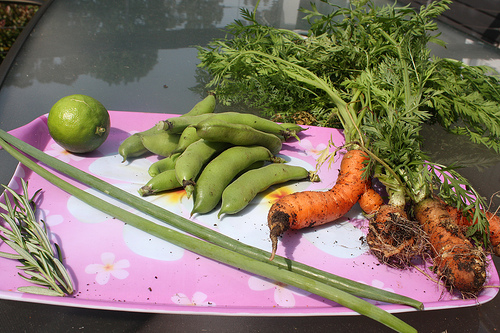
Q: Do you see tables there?
A: Yes, there is a table.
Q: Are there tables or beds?
A: Yes, there is a table.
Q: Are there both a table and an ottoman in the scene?
A: No, there is a table but no ottomen.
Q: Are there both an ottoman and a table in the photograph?
A: No, there is a table but no ottomen.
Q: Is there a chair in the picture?
A: No, there are no chairs.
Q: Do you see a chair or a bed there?
A: No, there are no chairs or beds.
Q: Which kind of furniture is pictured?
A: The furniture is a table.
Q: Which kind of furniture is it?
A: The piece of furniture is a table.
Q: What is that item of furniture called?
A: This is a table.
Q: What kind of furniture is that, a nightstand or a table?
A: This is a table.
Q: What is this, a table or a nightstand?
A: This is a table.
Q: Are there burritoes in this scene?
A: No, there are no burritoes.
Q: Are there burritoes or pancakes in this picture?
A: No, there are no burritoes or pancakes.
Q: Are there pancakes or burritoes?
A: No, there are no burritoes or pancakes.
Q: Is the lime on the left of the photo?
A: Yes, the lime is on the left of the image.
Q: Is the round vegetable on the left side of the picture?
A: Yes, the lime is on the left of the image.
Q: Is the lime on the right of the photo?
A: No, the lime is on the left of the image.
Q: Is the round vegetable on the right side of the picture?
A: No, the lime is on the left of the image.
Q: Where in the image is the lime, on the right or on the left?
A: The lime is on the left of the image.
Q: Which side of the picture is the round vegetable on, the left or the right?
A: The lime is on the left of the image.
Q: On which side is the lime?
A: The lime is on the left of the image.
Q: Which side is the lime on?
A: The lime is on the left of the image.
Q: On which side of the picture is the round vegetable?
A: The lime is on the left of the image.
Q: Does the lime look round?
A: Yes, the lime is round.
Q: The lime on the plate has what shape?
A: The lime is round.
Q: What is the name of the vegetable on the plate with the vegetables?
A: The vegetable is a lime.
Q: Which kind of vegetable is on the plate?
A: The vegetable is a lime.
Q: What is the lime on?
A: The lime is on the plate.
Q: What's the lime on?
A: The lime is on the plate.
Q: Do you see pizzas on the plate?
A: No, there is a lime on the plate.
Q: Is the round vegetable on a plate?
A: Yes, the lime is on a plate.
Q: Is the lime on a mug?
A: No, the lime is on a plate.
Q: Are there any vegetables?
A: Yes, there are vegetables.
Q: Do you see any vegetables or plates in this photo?
A: Yes, there are vegetables.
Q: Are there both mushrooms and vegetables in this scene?
A: No, there are vegetables but no mushrooms.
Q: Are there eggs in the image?
A: No, there are no eggs.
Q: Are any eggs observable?
A: No, there are no eggs.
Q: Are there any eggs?
A: No, there are no eggs.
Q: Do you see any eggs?
A: No, there are no eggs.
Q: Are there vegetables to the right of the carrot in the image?
A: Yes, there are vegetables to the right of the carrot.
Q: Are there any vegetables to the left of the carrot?
A: No, the vegetables are to the right of the carrot.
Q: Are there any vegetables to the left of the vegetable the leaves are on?
A: No, the vegetables are to the right of the carrot.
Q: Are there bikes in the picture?
A: No, there are no bikes.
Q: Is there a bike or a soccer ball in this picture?
A: No, there are no bikes or soccer balls.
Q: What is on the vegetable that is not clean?
A: The leaves are on the carrot.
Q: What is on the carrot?
A: The leaves are on the carrot.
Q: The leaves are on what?
A: The leaves are on the carrot.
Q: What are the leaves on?
A: The leaves are on the carrot.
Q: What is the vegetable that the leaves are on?
A: The vegetable is a carrot.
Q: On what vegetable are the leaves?
A: The leaves are on the carrot.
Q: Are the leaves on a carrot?
A: Yes, the leaves are on a carrot.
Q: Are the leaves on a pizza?
A: No, the leaves are on a carrot.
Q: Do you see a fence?
A: No, there are no fences.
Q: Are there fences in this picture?
A: No, there are no fences.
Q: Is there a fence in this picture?
A: No, there are no fences.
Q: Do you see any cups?
A: No, there are no cups.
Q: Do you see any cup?
A: No, there are no cups.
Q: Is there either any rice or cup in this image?
A: No, there are no cups or rice.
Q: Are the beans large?
A: Yes, the beans are large.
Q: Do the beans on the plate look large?
A: Yes, the beans are large.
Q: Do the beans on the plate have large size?
A: Yes, the beans are large.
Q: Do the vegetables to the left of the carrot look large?
A: Yes, the beans are large.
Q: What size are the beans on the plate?
A: The beans are large.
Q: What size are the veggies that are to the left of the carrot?
A: The beans are large.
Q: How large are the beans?
A: The beans are large.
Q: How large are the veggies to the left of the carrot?
A: The beans are large.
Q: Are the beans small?
A: No, the beans are large.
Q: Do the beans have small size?
A: No, the beans are large.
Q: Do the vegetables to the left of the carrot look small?
A: No, the beans are large.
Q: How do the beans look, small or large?
A: The beans are large.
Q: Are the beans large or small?
A: The beans are large.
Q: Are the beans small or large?
A: The beans are large.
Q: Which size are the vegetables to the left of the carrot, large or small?
A: The beans are large.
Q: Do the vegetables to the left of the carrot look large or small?
A: The beans are large.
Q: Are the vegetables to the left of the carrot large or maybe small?
A: The beans are large.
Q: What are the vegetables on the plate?
A: The vegetables are beans.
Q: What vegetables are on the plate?
A: The vegetables are beans.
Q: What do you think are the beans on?
A: The beans are on the plate.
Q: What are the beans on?
A: The beans are on the plate.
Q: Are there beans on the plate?
A: Yes, there are beans on the plate.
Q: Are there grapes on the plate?
A: No, there are beans on the plate.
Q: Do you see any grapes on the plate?
A: No, there are beans on the plate.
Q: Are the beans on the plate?
A: Yes, the beans are on the plate.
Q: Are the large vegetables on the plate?
A: Yes, the beans are on the plate.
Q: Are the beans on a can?
A: No, the beans are on the plate.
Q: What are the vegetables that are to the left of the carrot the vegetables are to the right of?
A: The vegetables are beans.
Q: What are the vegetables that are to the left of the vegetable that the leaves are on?
A: The vegetables are beans.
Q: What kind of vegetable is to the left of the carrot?
A: The vegetables are beans.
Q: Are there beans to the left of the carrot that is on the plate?
A: Yes, there are beans to the left of the carrot.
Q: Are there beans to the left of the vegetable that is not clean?
A: Yes, there are beans to the left of the carrot.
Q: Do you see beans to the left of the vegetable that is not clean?
A: Yes, there are beans to the left of the carrot.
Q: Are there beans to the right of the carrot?
A: No, the beans are to the left of the carrot.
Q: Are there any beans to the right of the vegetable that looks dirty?
A: No, the beans are to the left of the carrot.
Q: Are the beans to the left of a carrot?
A: Yes, the beans are to the left of a carrot.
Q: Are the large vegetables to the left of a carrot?
A: Yes, the beans are to the left of a carrot.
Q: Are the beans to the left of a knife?
A: No, the beans are to the left of a carrot.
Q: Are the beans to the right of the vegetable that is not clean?
A: No, the beans are to the left of the carrot.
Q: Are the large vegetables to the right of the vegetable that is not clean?
A: No, the beans are to the left of the carrot.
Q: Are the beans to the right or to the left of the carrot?
A: The beans are to the left of the carrot.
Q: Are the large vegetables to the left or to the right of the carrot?
A: The beans are to the left of the carrot.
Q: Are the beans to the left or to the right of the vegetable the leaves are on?
A: The beans are to the left of the carrot.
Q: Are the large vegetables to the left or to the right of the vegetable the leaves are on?
A: The beans are to the left of the carrot.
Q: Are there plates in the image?
A: Yes, there is a plate.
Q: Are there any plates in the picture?
A: Yes, there is a plate.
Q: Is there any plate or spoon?
A: Yes, there is a plate.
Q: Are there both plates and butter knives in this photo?
A: No, there is a plate but no butter knives.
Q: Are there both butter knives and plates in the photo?
A: No, there is a plate but no butter knives.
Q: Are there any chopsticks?
A: No, there are no chopsticks.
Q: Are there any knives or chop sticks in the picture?
A: No, there are no chop sticks or knives.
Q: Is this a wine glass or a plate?
A: This is a plate.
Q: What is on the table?
A: The plate is on the table.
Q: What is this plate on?
A: The plate is on the table.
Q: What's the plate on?
A: The plate is on the table.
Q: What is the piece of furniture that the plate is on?
A: The piece of furniture is a table.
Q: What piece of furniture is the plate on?
A: The plate is on the table.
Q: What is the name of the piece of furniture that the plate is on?
A: The piece of furniture is a table.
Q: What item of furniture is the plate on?
A: The plate is on the table.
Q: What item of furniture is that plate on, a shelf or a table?
A: The plate is on a table.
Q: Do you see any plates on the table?
A: Yes, there is a plate on the table.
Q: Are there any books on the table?
A: No, there is a plate on the table.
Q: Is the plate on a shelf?
A: No, the plate is on the table.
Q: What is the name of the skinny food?
A: The food is a vegetable.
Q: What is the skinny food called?
A: The food is a vegetable.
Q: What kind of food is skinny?
A: The food is a vegetable.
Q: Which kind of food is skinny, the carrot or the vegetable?
A: The vegetable is skinny.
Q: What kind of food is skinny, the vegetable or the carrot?
A: The vegetable is skinny.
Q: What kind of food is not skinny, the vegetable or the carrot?
A: The carrot is not skinny.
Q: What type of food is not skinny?
A: The food is a carrot.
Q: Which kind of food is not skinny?
A: The food is a carrot.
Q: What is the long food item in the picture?
A: The food item is a vegetable.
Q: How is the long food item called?
A: The food item is a vegetable.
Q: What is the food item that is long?
A: The food item is a vegetable.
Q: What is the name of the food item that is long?
A: The food item is a vegetable.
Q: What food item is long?
A: The food item is a vegetable.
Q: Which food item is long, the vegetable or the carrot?
A: The vegetable is long.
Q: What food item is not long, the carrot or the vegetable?
A: The carrot is not long.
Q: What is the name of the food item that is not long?
A: The food item is a carrot.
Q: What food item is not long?
A: The food item is a carrot.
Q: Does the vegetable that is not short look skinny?
A: Yes, the vegetable is skinny.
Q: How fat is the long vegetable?
A: The vegetable is skinny.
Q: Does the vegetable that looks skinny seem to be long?
A: Yes, the vegetable is long.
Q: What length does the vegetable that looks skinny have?
A: The vegetable has long length.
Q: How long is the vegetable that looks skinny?
A: The vegetable is long.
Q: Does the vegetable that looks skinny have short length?
A: No, the vegetable is long.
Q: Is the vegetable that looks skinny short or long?
A: The vegetable is long.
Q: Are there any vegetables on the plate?
A: Yes, there is a vegetable on the plate.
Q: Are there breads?
A: No, there are no breads.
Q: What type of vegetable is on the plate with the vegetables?
A: The vegetable is a herb.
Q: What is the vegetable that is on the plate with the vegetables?
A: The vegetable is a herb.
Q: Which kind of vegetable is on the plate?
A: The vegetable is a herb.